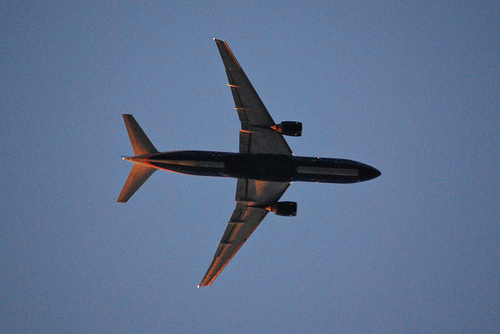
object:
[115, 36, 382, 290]
airplane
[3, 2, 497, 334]
sky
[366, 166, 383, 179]
nose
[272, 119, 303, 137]
engine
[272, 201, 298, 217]
engine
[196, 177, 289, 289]
left wing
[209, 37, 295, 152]
right wing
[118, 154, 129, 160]
tail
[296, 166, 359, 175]
area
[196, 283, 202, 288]
light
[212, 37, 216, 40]
light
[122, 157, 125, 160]
light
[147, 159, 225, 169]
line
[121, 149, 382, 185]
body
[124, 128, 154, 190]
reflection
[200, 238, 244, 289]
reflection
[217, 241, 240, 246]
aileron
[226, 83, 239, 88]
aileron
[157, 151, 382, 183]
underside